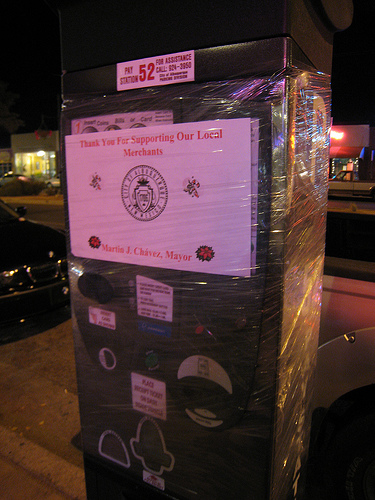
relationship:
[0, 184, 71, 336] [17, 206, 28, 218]
car has side mirror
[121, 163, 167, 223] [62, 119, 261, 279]
picture on sign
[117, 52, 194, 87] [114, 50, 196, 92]
letter on sign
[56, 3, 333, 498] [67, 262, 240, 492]
package has stickers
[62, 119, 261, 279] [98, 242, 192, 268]
sticker has mayor's name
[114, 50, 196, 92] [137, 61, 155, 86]
sticker has printed number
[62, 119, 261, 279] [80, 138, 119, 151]
sign says thank you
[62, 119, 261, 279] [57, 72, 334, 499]
sign under plastic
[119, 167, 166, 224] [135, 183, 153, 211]
symbol of city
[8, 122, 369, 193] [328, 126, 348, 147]
building has light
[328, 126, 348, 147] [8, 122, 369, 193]
light on building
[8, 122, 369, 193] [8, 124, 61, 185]
building has store front